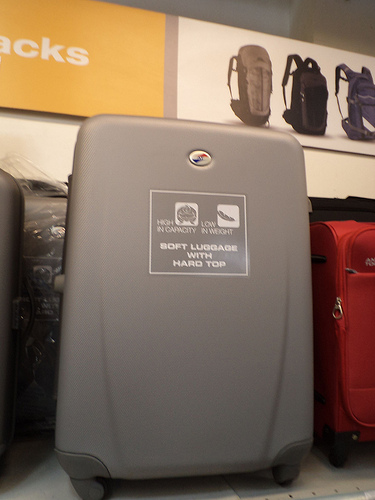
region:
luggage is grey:
[86, 113, 286, 472]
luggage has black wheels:
[77, 462, 317, 497]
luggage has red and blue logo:
[178, 134, 206, 167]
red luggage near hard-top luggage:
[299, 220, 367, 458]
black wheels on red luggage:
[324, 433, 357, 481]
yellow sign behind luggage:
[24, 1, 152, 112]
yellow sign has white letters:
[24, 6, 142, 105]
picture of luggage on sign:
[210, 38, 374, 156]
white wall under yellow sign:
[2, 98, 101, 185]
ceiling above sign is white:
[259, 1, 352, 51]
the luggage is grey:
[116, 355, 214, 449]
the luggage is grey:
[65, 306, 167, 420]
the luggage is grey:
[114, 380, 243, 481]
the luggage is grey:
[184, 391, 246, 474]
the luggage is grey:
[126, 355, 192, 417]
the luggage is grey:
[118, 288, 190, 400]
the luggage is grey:
[152, 326, 220, 456]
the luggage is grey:
[201, 450, 228, 498]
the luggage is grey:
[143, 381, 190, 430]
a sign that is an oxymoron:
[142, 186, 252, 281]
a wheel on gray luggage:
[260, 452, 303, 488]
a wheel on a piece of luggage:
[67, 466, 124, 498]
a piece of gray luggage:
[35, 112, 329, 481]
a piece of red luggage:
[310, 204, 373, 464]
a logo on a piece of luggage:
[180, 144, 221, 172]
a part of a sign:
[4, 0, 173, 126]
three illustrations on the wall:
[223, 40, 374, 144]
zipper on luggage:
[326, 293, 349, 324]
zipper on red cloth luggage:
[328, 293, 347, 338]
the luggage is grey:
[160, 291, 250, 414]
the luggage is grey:
[157, 439, 200, 496]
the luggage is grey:
[144, 394, 213, 474]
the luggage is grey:
[105, 360, 186, 487]